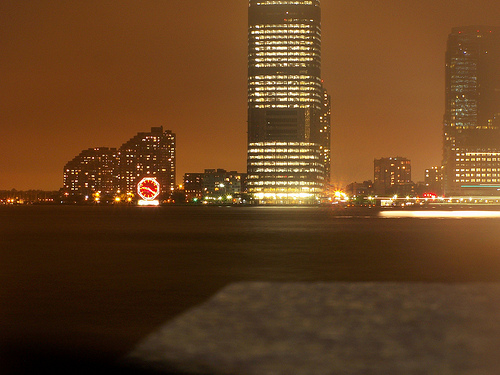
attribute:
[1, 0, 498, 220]
skyline — city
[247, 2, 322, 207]
skyscraper — tall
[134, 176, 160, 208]
street light — bright 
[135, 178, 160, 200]
clock — red 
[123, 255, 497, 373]
asphalt top — gray 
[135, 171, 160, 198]
hands — white 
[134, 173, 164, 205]
clock — red, white 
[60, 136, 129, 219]
building — large 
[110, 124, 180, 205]
building — large 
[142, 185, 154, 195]
minute hand — white 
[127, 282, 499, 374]
stone object — large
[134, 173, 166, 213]
clock — white 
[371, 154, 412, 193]
building — large 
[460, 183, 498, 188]
light — green 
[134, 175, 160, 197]
clock — white, round, large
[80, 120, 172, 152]
roof — uneven 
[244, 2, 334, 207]
building — Tall , dark 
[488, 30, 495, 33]
red light — red 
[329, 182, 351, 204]
light — shiny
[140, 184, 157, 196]
hands — white 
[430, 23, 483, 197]
skyscraper — tall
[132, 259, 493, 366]
cover — wide 